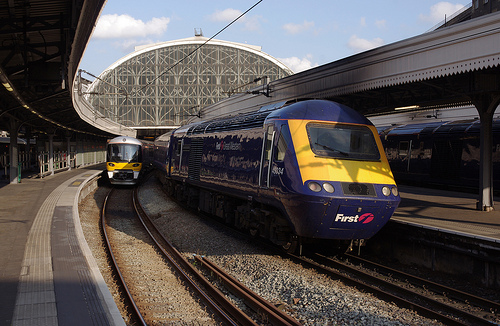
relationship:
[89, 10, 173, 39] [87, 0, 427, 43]
cloud in sky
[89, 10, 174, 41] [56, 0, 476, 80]
cloud in sky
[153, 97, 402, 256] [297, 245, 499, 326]
train on a track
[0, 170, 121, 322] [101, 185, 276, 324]
sidewalk next to track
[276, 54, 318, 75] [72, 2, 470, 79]
white clouds in blue sky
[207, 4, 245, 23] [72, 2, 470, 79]
cloud in blue sky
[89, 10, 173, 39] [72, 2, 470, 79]
cloud in blue sky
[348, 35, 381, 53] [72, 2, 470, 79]
white clouds in blue sky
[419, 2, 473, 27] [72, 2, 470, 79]
white clouds in blue sky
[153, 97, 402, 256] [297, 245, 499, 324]
train on track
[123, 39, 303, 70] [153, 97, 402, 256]
power line above train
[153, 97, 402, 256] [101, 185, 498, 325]
train on track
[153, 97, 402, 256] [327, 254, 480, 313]
train on track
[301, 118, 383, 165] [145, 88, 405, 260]
windshield on train